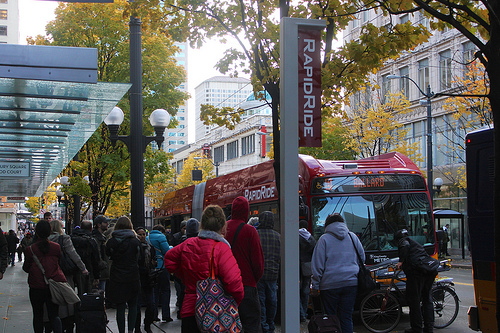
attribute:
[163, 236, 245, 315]
jacket — red, pink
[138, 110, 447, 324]
bus — red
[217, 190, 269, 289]
hoodie — red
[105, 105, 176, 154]
lamps — dual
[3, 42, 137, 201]
roof — plexi glass, clear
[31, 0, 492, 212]
leaves — yellow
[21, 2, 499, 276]
trees — gren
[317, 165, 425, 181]
lights — orange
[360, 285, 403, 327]
wheel — back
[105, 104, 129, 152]
street light — white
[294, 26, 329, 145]
sign — bus stop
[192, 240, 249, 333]
purse — woman's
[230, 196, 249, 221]
hood — red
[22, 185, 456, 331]
passengers — bus'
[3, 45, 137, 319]
stand — bus stop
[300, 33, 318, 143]
color — red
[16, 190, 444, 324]
group — people, waiting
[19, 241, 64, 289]
shirt — red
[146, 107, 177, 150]
street light — white